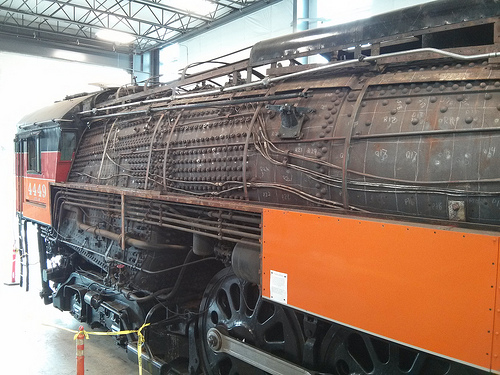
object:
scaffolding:
[0, 0, 315, 65]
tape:
[13, 248, 152, 375]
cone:
[74, 325, 83, 375]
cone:
[4, 242, 21, 286]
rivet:
[182, 110, 189, 118]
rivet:
[237, 175, 243, 180]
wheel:
[322, 315, 486, 375]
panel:
[258, 207, 500, 375]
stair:
[17, 211, 30, 292]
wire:
[105, 150, 371, 214]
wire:
[70, 170, 347, 212]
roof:
[1, 0, 282, 73]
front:
[14, 82, 157, 228]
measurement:
[375, 148, 389, 162]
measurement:
[405, 150, 417, 163]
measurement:
[383, 116, 399, 129]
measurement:
[411, 96, 427, 117]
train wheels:
[187, 265, 480, 375]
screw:
[271, 272, 274, 275]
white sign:
[269, 270, 287, 305]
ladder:
[18, 216, 28, 291]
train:
[0, 0, 497, 375]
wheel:
[197, 274, 312, 371]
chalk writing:
[376, 95, 460, 164]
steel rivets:
[68, 99, 269, 199]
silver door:
[0, 37, 134, 72]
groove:
[229, 282, 240, 311]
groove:
[243, 281, 261, 318]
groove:
[263, 321, 285, 344]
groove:
[256, 300, 277, 325]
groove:
[211, 310, 218, 323]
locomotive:
[0, 0, 500, 375]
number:
[28, 183, 46, 198]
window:
[27, 139, 36, 174]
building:
[1, 0, 500, 375]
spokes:
[216, 282, 276, 326]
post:
[73, 324, 87, 375]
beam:
[0, 0, 259, 54]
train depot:
[13, 0, 500, 375]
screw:
[207, 330, 222, 350]